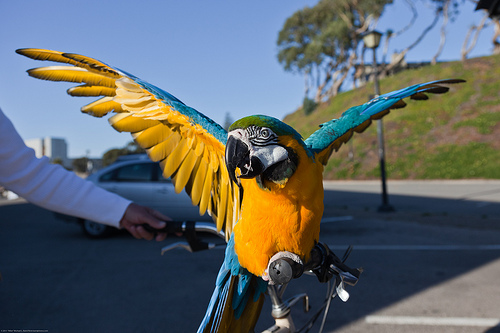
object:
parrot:
[14, 45, 472, 333]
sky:
[0, 1, 499, 159]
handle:
[131, 220, 197, 236]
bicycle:
[135, 217, 368, 332]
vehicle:
[50, 153, 229, 241]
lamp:
[354, 28, 383, 51]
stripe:
[327, 243, 500, 253]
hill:
[280, 52, 500, 185]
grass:
[281, 53, 500, 183]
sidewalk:
[317, 178, 500, 237]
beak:
[222, 134, 267, 188]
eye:
[257, 128, 271, 140]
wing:
[304, 77, 468, 170]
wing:
[8, 46, 228, 237]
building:
[23, 135, 70, 166]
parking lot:
[0, 178, 500, 332]